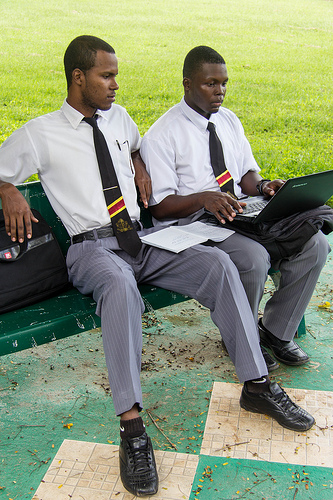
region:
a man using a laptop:
[141, 45, 332, 369]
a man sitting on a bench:
[1, 34, 317, 494]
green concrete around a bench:
[0, 227, 331, 498]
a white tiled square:
[198, 381, 331, 469]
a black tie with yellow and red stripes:
[84, 114, 146, 258]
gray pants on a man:
[67, 221, 270, 416]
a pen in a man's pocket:
[113, 137, 124, 152]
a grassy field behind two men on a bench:
[0, 2, 330, 185]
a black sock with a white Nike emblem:
[114, 413, 149, 443]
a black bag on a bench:
[0, 198, 73, 308]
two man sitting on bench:
[44, 29, 311, 302]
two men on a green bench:
[1, 68, 326, 323]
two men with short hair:
[22, 35, 260, 193]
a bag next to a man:
[5, 168, 197, 355]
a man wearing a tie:
[35, 48, 180, 239]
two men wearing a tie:
[43, 15, 332, 251]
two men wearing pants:
[35, 45, 326, 329]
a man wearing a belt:
[13, 73, 227, 354]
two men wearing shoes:
[59, 41, 330, 363]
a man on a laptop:
[144, 32, 331, 283]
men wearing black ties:
[78, 101, 244, 220]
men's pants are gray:
[57, 174, 329, 345]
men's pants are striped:
[53, 206, 320, 355]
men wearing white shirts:
[0, 89, 279, 226]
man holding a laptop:
[204, 149, 329, 233]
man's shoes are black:
[93, 377, 318, 494]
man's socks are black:
[61, 333, 303, 427]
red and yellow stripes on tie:
[102, 185, 134, 231]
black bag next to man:
[0, 203, 72, 311]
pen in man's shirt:
[113, 129, 125, 154]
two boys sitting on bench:
[23, 29, 313, 487]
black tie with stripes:
[74, 122, 147, 265]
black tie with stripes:
[202, 127, 233, 192]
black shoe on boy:
[248, 389, 321, 446]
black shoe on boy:
[108, 422, 161, 490]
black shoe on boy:
[272, 340, 303, 373]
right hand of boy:
[0, 208, 41, 243]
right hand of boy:
[195, 193, 238, 225]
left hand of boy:
[135, 172, 155, 211]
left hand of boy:
[257, 168, 280, 194]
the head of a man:
[58, 31, 126, 113]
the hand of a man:
[0, 183, 42, 245]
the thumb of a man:
[27, 205, 41, 224]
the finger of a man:
[22, 211, 34, 240]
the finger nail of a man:
[26, 230, 34, 240]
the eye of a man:
[99, 70, 112, 81]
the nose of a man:
[106, 74, 121, 91]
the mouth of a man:
[104, 91, 118, 100]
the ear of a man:
[71, 65, 87, 90]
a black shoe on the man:
[117, 426, 163, 497]